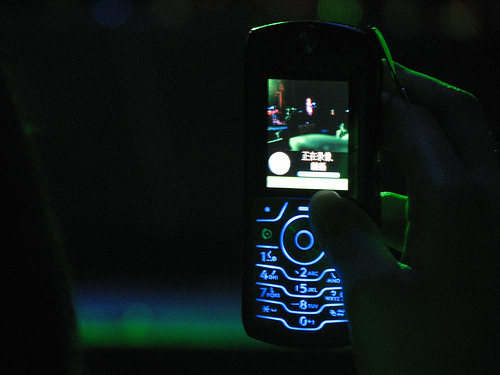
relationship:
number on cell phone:
[260, 270, 269, 280] [243, 19, 381, 349]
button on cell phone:
[256, 201, 350, 332] [234, 13, 389, 355]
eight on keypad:
[285, 290, 318, 318] [206, 189, 380, 357]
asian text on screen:
[297, 148, 343, 165] [259, 65, 363, 197]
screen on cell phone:
[265, 75, 355, 201] [243, 19, 381, 349]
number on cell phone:
[299, 267, 308, 278] [238, 17, 374, 349]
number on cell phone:
[297, 282, 306, 294] [238, 17, 374, 349]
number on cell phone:
[298, 300, 308, 309] [238, 17, 374, 349]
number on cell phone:
[299, 315, 307, 325] [238, 17, 374, 349]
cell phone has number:
[238, 17, 374, 349] [258, 285, 268, 298]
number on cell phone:
[259, 250, 266, 263] [238, 17, 374, 349]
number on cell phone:
[258, 268, 268, 281] [238, 17, 374, 349]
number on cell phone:
[299, 266, 308, 278] [238, 17, 374, 349]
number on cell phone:
[299, 283, 307, 294] [238, 17, 374, 349]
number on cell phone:
[258, 287, 268, 297] [238, 17, 374, 349]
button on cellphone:
[256, 201, 350, 332] [234, 14, 392, 352]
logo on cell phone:
[300, 147, 333, 162] [243, 19, 381, 349]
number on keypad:
[260, 251, 266, 262] [249, 198, 349, 338]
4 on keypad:
[255, 260, 286, 286] [250, 257, 325, 316]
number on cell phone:
[337, 290, 343, 297] [243, 19, 381, 349]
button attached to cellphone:
[256, 201, 350, 332] [245, 14, 377, 346]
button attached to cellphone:
[256, 201, 350, 332] [234, 14, 392, 352]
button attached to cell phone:
[256, 201, 350, 332] [238, 17, 374, 349]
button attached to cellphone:
[323, 304, 348, 321] [237, 22, 360, 349]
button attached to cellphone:
[256, 201, 350, 332] [243, 19, 380, 369]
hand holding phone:
[305, 56, 484, 373] [226, 7, 398, 362]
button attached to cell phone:
[256, 201, 350, 332] [243, 19, 381, 349]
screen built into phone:
[265, 75, 355, 201] [247, 47, 364, 342]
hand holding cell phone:
[305, 56, 484, 373] [243, 19, 381, 349]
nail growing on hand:
[307, 192, 337, 228] [305, 56, 484, 373]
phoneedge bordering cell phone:
[241, 35, 253, 342] [243, 19, 381, 349]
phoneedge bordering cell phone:
[248, 12, 370, 32] [243, 19, 381, 349]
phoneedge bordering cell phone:
[363, 37, 381, 216] [243, 19, 381, 349]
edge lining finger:
[305, 215, 347, 315] [311, 197, 388, 279]